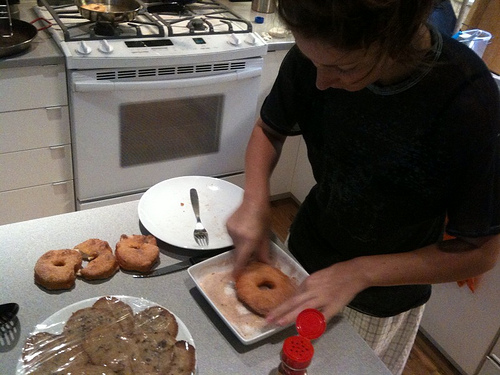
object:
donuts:
[72, 232, 120, 286]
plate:
[17, 295, 200, 375]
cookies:
[130, 306, 178, 345]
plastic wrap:
[17, 295, 200, 374]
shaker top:
[280, 309, 326, 370]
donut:
[230, 260, 304, 321]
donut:
[35, 248, 81, 290]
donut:
[116, 233, 160, 274]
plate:
[137, 173, 249, 253]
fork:
[188, 188, 211, 249]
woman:
[226, 0, 500, 374]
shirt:
[259, 23, 498, 316]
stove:
[34, 0, 267, 212]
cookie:
[128, 334, 174, 374]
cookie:
[86, 324, 130, 369]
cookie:
[23, 332, 60, 367]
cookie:
[66, 307, 120, 349]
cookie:
[94, 295, 132, 327]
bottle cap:
[254, 15, 263, 23]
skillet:
[76, 1, 181, 26]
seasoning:
[277, 308, 326, 374]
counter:
[1, 200, 393, 374]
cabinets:
[0, 65, 76, 226]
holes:
[290, 339, 297, 345]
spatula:
[0, 302, 19, 328]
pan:
[0, 16, 53, 60]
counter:
[0, 0, 66, 69]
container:
[451, 29, 492, 58]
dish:
[187, 239, 312, 345]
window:
[118, 92, 226, 168]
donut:
[82, 3, 107, 13]